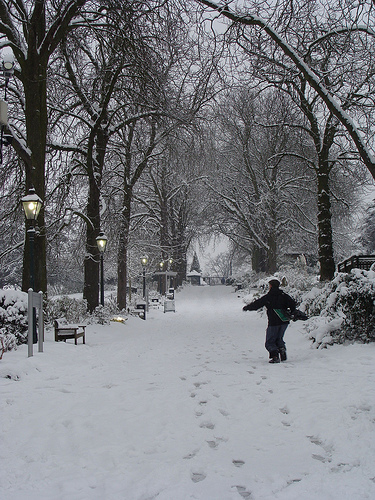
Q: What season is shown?
A: Winter.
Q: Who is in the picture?
A: A snowboarder.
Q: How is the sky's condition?
A: Gray and snowy.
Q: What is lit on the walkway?
A: Street lights.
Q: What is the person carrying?
A: A snowboard.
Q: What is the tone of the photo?
A: Retro black and white.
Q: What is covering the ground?
A: Snow.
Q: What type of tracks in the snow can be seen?
A: Shoe prints.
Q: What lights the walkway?
A: Lamps.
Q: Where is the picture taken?
A: A park.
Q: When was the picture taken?
A: During the day.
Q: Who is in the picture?
A: One person.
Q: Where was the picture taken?
A: On a snowy sidewalk.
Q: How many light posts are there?
A: Five.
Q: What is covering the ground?
A: Snow.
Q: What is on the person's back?
A: A satchel.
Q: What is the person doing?
A: Walking in the snow.